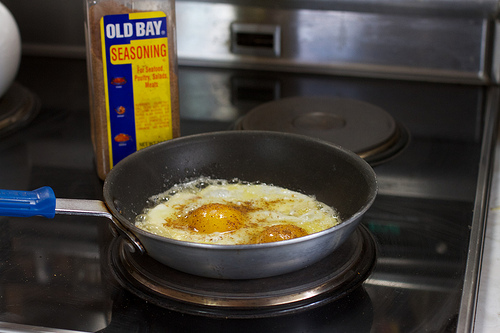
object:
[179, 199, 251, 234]
eggs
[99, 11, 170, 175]
label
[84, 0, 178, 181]
seasoning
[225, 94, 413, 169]
burner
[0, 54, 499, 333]
stove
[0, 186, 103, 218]
handle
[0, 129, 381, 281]
pan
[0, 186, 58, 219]
protective covering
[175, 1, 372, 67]
reflection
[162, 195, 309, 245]
seasoning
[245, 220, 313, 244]
egg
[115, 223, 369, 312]
plate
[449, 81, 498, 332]
border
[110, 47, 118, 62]
words